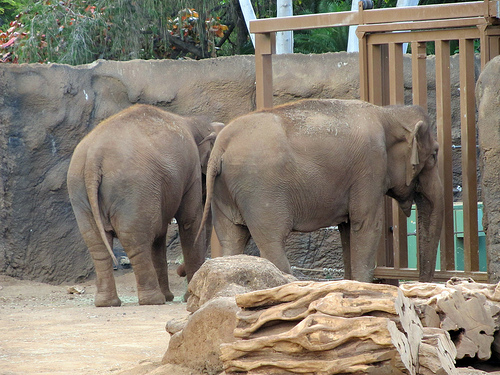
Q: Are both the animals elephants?
A: Yes, all the animals are elephants.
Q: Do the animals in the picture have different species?
A: No, all the animals are elephants.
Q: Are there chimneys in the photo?
A: No, there are no chimneys.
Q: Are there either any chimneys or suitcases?
A: No, there are no chimneys or suitcases.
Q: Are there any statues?
A: No, there are no statues.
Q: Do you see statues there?
A: No, there are no statues.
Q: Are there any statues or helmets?
A: No, there are no statues or helmets.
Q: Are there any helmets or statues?
A: No, there are no statues or helmets.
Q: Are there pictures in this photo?
A: No, there are no pictures.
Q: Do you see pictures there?
A: No, there are no pictures.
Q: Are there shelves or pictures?
A: No, there are no pictures or shelves.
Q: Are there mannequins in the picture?
A: No, there are no mannequins.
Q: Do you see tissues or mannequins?
A: No, there are no mannequins or tissues.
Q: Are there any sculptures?
A: No, there are no sculptures.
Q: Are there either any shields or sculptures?
A: No, there are no sculptures or shields.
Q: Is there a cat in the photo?
A: No, there are no cats.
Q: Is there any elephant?
A: Yes, there is an elephant.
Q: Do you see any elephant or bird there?
A: Yes, there is an elephant.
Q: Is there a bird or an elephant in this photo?
A: Yes, there is an elephant.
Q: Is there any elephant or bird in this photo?
A: Yes, there is an elephant.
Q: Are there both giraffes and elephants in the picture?
A: No, there is an elephant but no giraffes.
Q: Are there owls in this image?
A: No, there are no owls.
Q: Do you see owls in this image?
A: No, there are no owls.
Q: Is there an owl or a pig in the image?
A: No, there are no owls or pigs.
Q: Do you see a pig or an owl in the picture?
A: No, there are no owls or pigs.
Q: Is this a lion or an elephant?
A: This is an elephant.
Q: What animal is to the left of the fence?
A: The animal is an elephant.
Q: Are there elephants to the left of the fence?
A: Yes, there is an elephant to the left of the fence.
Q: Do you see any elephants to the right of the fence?
A: No, the elephant is to the left of the fence.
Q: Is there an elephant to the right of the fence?
A: No, the elephant is to the left of the fence.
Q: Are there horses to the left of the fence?
A: No, there is an elephant to the left of the fence.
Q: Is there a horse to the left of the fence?
A: No, there is an elephant to the left of the fence.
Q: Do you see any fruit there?
A: Yes, there is a fruit.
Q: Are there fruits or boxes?
A: Yes, there is a fruit.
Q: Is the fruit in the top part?
A: Yes, the fruit is in the top of the image.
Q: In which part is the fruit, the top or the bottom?
A: The fruit is in the top of the image.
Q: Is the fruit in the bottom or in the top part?
A: The fruit is in the top of the image.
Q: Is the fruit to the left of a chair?
A: No, the fruit is to the left of the fence.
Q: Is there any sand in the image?
A: Yes, there is sand.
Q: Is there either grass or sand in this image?
A: Yes, there is sand.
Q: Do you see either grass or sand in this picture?
A: Yes, there is sand.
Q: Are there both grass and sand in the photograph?
A: Yes, there are both sand and grass.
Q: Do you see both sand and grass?
A: Yes, there are both sand and grass.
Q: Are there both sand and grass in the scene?
A: Yes, there are both sand and grass.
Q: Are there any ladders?
A: No, there are no ladders.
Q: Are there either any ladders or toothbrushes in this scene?
A: No, there are no ladders or toothbrushes.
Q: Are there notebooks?
A: No, there are no notebooks.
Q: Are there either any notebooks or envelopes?
A: No, there are no notebooks or envelopes.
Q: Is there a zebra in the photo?
A: No, there are no zebras.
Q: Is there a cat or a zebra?
A: No, there are no zebras or cats.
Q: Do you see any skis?
A: No, there are no skis.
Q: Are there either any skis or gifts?
A: No, there are no skis or gifts.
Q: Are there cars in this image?
A: No, there are no cars.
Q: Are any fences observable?
A: Yes, there is a fence.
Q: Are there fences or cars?
A: Yes, there is a fence.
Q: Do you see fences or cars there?
A: Yes, there is a fence.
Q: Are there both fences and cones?
A: No, there is a fence but no cones.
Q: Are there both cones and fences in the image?
A: No, there is a fence but no cones.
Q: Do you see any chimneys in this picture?
A: No, there are no chimneys.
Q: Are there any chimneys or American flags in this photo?
A: No, there are no chimneys or American flags.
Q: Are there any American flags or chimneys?
A: No, there are no chimneys or American flags.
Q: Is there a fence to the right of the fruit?
A: Yes, there is a fence to the right of the fruit.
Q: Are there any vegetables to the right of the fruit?
A: No, there is a fence to the right of the fruit.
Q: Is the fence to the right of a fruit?
A: Yes, the fence is to the right of a fruit.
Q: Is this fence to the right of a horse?
A: No, the fence is to the right of a fruit.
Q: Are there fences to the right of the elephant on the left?
A: Yes, there is a fence to the right of the elephant.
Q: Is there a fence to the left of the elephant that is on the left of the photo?
A: No, the fence is to the right of the elephant.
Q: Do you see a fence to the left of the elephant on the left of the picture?
A: No, the fence is to the right of the elephant.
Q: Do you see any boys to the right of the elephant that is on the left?
A: No, there is a fence to the right of the elephant.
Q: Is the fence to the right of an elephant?
A: Yes, the fence is to the right of an elephant.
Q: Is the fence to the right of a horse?
A: No, the fence is to the right of an elephant.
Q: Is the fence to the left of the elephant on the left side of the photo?
A: No, the fence is to the right of the elephant.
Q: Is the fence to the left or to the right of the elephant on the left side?
A: The fence is to the right of the elephant.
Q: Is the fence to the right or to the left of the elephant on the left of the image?
A: The fence is to the right of the elephant.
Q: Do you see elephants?
A: Yes, there is an elephant.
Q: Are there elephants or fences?
A: Yes, there is an elephant.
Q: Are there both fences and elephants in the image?
A: Yes, there are both an elephant and a fence.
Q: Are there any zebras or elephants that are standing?
A: Yes, the elephant is standing.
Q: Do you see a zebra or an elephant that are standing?
A: Yes, the elephant is standing.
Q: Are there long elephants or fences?
A: Yes, there is a long elephant.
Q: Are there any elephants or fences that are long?
A: Yes, the elephant is long.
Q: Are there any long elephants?
A: Yes, there is a long elephant.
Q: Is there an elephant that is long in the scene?
A: Yes, there is a long elephant.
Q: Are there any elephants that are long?
A: Yes, there is an elephant that is long.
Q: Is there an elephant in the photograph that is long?
A: Yes, there is an elephant that is long.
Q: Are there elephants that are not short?
A: Yes, there is a long elephant.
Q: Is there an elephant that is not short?
A: Yes, there is a long elephant.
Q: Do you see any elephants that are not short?
A: Yes, there is a long elephant.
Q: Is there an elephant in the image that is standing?
A: Yes, there is an elephant that is standing.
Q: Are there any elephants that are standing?
A: Yes, there is an elephant that is standing.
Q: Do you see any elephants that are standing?
A: Yes, there is an elephant that is standing.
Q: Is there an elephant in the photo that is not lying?
A: Yes, there is an elephant that is standing.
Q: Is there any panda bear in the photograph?
A: No, there are no panda bears.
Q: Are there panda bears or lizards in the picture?
A: No, there are no panda bears or lizards.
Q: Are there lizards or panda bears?
A: No, there are no panda bears or lizards.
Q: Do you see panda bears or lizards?
A: No, there are no panda bears or lizards.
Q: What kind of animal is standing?
A: The animal is an elephant.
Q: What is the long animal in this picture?
A: The animal is an elephant.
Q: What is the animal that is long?
A: The animal is an elephant.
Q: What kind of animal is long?
A: The animal is an elephant.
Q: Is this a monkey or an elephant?
A: This is an elephant.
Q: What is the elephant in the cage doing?
A: The elephant is standing.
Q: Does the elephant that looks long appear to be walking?
A: No, the elephant is standing.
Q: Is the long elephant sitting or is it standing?
A: The elephant is standing.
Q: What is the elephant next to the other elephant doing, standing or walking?
A: The elephant is standing.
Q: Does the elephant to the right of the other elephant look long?
A: Yes, the elephant is long.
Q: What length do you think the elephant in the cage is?
A: The elephant is long.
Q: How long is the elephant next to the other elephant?
A: The elephant is long.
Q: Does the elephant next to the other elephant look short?
A: No, the elephant is long.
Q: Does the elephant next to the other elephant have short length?
A: No, the elephant is long.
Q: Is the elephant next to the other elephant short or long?
A: The elephant is long.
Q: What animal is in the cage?
A: The elephant is in the cage.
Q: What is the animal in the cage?
A: The animal is an elephant.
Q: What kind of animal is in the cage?
A: The animal is an elephant.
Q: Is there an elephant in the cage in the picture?
A: Yes, there is an elephant in the cage.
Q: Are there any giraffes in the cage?
A: No, there is an elephant in the cage.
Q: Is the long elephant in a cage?
A: Yes, the elephant is in a cage.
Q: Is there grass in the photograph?
A: Yes, there is grass.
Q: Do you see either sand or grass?
A: Yes, there is grass.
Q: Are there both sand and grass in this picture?
A: Yes, there are both grass and sand.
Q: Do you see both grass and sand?
A: Yes, there are both grass and sand.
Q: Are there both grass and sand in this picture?
A: Yes, there are both grass and sand.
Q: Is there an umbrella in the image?
A: No, there are no umbrellas.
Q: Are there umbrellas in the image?
A: No, there are no umbrellas.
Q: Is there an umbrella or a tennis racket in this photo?
A: No, there are no umbrellas or rackets.